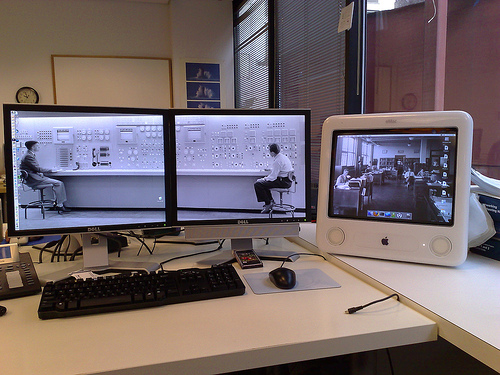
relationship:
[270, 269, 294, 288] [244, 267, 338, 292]
mouse on pad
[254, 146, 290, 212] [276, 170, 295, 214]
man sitting on stool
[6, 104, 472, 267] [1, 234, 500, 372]
computers on desk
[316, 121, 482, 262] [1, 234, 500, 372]
monitor on desk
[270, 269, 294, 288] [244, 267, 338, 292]
mouse on mousepad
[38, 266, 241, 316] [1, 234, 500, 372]
keyboard on desk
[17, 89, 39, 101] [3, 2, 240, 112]
clock on wall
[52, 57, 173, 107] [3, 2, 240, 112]
board on wall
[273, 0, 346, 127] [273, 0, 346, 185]
blinds on blinds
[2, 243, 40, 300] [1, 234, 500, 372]
telephone on desk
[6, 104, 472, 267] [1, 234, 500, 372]
monitors on desk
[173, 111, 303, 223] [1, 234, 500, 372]
monitor on table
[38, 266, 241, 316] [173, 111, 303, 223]
keyboard in front of monitor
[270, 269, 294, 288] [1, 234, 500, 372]
mouse on desk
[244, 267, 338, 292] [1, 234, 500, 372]
pad on desk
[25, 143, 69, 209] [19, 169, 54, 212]
man sitting in stool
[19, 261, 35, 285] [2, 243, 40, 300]
buttons on telephone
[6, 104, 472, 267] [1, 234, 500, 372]
computers on top of desk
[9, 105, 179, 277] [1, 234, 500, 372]
computer on desk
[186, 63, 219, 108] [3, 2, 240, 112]
poster on wall